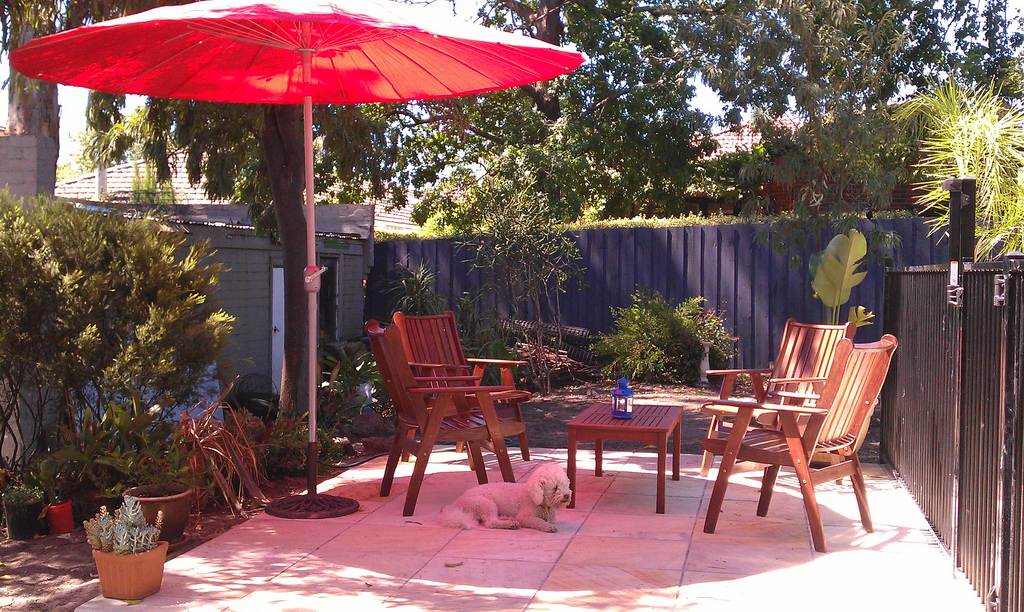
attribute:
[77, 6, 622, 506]
umbrella — open, large, red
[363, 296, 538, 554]
chair — red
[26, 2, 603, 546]
umbrella — red, open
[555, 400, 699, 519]
table — small, brown, wooden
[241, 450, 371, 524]
umbrella stand — black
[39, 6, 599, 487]
umbrella — large, red